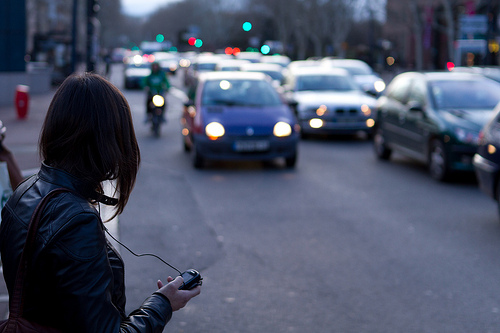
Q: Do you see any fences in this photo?
A: No, there are no fences.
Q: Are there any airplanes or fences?
A: No, there are no fences or airplanes.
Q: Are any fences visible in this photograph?
A: No, there are no fences.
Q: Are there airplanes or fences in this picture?
A: No, there are no fences or airplanes.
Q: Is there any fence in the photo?
A: No, there are no fences.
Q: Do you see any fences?
A: No, there are no fences.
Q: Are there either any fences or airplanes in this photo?
A: No, there are no fences or airplanes.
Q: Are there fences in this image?
A: No, there are no fences.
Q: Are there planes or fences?
A: No, there are no fences or planes.